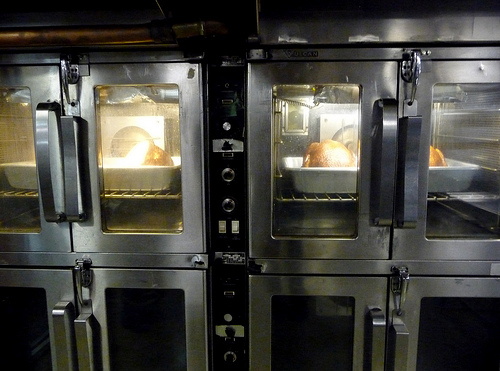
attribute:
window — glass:
[265, 67, 499, 254]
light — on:
[119, 148, 146, 165]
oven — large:
[246, 275, 498, 370]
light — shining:
[63, 69, 207, 209]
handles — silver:
[38, 101, 86, 226]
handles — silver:
[370, 92, 427, 231]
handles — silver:
[367, 311, 406, 369]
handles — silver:
[51, 292, 96, 364]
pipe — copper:
[6, 10, 220, 45]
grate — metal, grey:
[279, 186, 356, 207]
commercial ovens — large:
[1, 2, 498, 366]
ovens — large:
[17, 37, 489, 332]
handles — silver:
[48, 296, 98, 370]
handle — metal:
[375, 101, 395, 226]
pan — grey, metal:
[258, 129, 475, 209]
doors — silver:
[8, 47, 498, 369]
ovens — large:
[0, 1, 497, 367]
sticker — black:
[284, 47, 320, 59]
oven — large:
[4, 266, 204, 369]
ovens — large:
[4, 34, 499, 364]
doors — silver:
[253, 50, 496, 261]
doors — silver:
[256, 262, 479, 369]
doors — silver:
[3, 55, 202, 261]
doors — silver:
[8, 259, 219, 366]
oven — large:
[34, 67, 197, 242]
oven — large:
[296, 86, 488, 283]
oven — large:
[0, 43, 201, 265]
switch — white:
[213, 219, 250, 244]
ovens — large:
[52, 76, 470, 257]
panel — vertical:
[197, 60, 261, 369]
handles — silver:
[370, 88, 436, 265]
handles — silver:
[356, 306, 411, 365]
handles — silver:
[45, 295, 112, 360]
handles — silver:
[29, 97, 92, 257]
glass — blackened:
[265, 293, 496, 363]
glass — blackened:
[1, 287, 189, 367]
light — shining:
[80, 93, 180, 244]